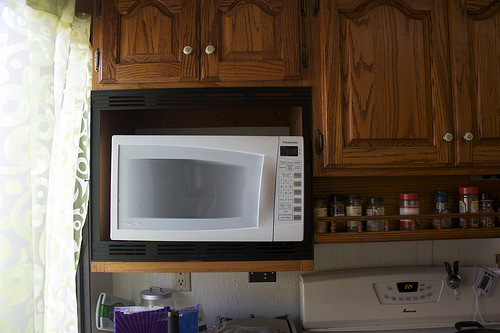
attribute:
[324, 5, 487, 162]
cabinet — wooden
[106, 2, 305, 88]
cabinet — wooden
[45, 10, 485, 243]
cabinets — wooden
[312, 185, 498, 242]
spice rack — wooden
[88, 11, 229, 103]
door — white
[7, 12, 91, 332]
curtains — patterned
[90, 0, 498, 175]
cabinets — wooden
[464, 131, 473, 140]
knob — white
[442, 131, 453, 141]
knob — white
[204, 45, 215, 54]
knob — white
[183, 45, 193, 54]
knob — white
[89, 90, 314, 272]
stand — built in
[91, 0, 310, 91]
cabinet — smaller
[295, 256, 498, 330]
oven — digital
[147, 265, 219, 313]
electrical outlet — tan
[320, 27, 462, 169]
cabinet — wooden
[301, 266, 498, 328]
oven — white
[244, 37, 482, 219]
cabin — brown, wood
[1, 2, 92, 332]
curtains — white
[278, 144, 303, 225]
display — digital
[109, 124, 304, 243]
oven — white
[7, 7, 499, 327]
kitchen — white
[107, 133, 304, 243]
microwave — white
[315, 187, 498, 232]
bottles — small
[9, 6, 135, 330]
curtain. — white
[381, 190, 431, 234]
bottle — red, white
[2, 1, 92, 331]
curtain — beautiful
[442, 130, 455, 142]
knob — white, round